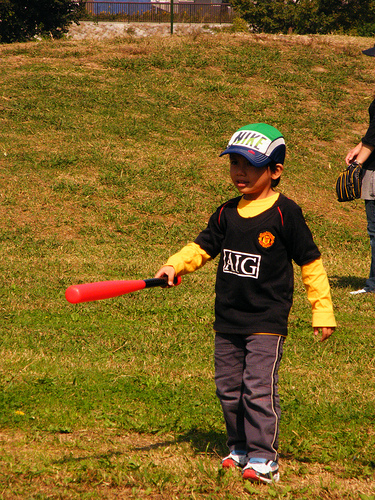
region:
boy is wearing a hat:
[202, 115, 313, 196]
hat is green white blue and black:
[212, 119, 295, 168]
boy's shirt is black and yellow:
[164, 178, 371, 339]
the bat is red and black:
[41, 240, 220, 349]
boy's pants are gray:
[201, 326, 319, 486]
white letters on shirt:
[207, 246, 274, 297]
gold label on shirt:
[251, 227, 277, 251]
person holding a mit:
[335, 149, 370, 206]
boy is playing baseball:
[53, 88, 291, 493]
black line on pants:
[259, 336, 287, 477]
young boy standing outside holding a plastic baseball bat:
[155, 122, 334, 482]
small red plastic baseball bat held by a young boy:
[64, 275, 183, 302]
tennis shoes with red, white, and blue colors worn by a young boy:
[218, 447, 279, 483]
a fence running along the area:
[75, 0, 256, 33]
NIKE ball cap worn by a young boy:
[218, 121, 287, 165]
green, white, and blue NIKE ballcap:
[217, 121, 286, 166]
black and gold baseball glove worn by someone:
[334, 158, 362, 201]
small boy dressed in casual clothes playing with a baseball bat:
[158, 122, 337, 477]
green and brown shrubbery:
[235, 1, 373, 35]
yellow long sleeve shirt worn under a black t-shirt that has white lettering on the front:
[158, 195, 336, 335]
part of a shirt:
[283, 283, 298, 311]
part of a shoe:
[245, 459, 258, 481]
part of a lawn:
[124, 453, 137, 476]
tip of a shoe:
[250, 470, 256, 473]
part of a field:
[110, 399, 134, 432]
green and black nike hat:
[210, 119, 302, 181]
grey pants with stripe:
[209, 319, 304, 482]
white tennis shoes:
[204, 439, 276, 488]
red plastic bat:
[52, 264, 208, 317]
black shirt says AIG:
[186, 196, 292, 352]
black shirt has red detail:
[214, 132, 315, 341]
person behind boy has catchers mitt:
[325, 84, 374, 254]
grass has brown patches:
[34, 334, 289, 499]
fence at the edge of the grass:
[84, 3, 237, 39]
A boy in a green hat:
[204, 112, 295, 204]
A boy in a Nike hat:
[216, 117, 299, 201]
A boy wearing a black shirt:
[189, 115, 335, 346]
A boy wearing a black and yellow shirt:
[161, 115, 345, 361]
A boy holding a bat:
[43, 217, 199, 316]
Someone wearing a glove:
[322, 150, 373, 210]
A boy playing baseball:
[42, 117, 341, 355]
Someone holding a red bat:
[57, 233, 202, 305]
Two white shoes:
[197, 423, 303, 491]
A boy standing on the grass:
[183, 114, 341, 493]